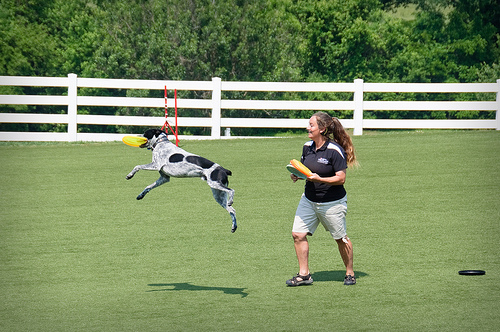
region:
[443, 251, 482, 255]
black disc on ground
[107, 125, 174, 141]
yellow frisbee in dog's mouth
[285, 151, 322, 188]
woman holding orange frisbee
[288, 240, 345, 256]
muscles on woman's foot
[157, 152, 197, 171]
black spots on dog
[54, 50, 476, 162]
white fence in the back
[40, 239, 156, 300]
well maintained green grass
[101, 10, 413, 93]
large forest of green trees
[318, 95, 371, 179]
woman with large pony tail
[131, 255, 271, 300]
shadow of dog on the grass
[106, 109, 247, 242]
dog jumping to catch a frisbee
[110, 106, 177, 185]
dog with frisbee in its mouth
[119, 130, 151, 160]
a yellow frisbee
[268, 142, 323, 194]
woman holding to frisbees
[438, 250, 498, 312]
a black frisbee on the grass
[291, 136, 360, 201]
woman wearing a black and white shirt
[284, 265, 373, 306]
woman wearing sandals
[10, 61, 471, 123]
a white wooden fence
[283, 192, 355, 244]
woman wearing tan shorts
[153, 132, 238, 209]
a white dog with black spots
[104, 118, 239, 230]
dog in the air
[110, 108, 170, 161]
dog has frisbee in it's mouth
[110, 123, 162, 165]
frisbee is yellow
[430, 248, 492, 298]
black frisbee on the grass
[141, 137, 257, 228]
dog is white and black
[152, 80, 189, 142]
red jump for tricks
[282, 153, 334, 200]
woman holding frisbees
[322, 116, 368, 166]
woman has a ponytail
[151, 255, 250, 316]
shadow of the dog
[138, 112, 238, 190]
dog has black spots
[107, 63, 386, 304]
a woman with her dog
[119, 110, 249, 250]
the dog has black spots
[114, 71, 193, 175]
the dog has a red leash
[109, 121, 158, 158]
the frisbee is yellow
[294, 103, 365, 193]
the woman has long hair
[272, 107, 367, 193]
the woman is carrying frisbees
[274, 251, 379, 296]
the sandals are black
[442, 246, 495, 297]
a black frisbee is on the grass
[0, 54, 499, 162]
the fence is white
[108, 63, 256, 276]
the dog is jumping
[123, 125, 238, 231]
Black and white dog leaping to catch frisbee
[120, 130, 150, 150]
Yellow frisbee in dog's mouth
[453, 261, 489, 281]
Black frisbee lying on grass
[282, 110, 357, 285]
Lady training frisbee dog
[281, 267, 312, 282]
Sandals on lady training frisbee dog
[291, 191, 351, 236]
White shorts on lady frisbee dog trainer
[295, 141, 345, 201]
Black shirt on lady frisbee dog trainer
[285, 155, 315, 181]
Two frisbees in hands of lady frisbee dog trainer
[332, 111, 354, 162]
Long, brown ponytail of lady frisbee dog trainer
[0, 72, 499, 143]
White fence enclosing field